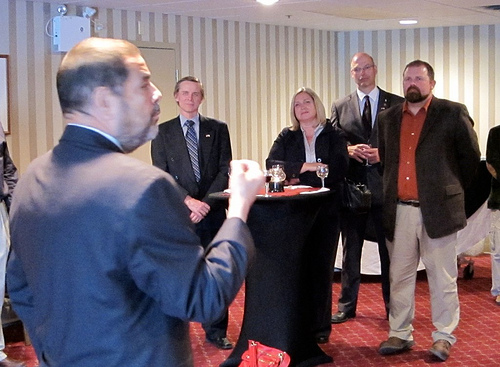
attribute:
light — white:
[399, 17, 419, 29]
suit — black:
[10, 132, 258, 364]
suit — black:
[156, 117, 230, 209]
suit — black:
[330, 92, 392, 317]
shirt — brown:
[335, 119, 493, 219]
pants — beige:
[388, 197, 461, 342]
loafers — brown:
[374, 323, 459, 365]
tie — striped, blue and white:
[179, 117, 203, 178]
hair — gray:
[56, 37, 141, 114]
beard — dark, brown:
[402, 81, 426, 108]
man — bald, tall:
[332, 41, 429, 293]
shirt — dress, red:
[396, 95, 434, 202]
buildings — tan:
[213, 35, 283, 110]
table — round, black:
[211, 182, 343, 365]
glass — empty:
[315, 161, 330, 188]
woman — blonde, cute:
[238, 57, 350, 336]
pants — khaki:
[377, 197, 464, 344]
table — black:
[195, 176, 335, 349]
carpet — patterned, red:
[262, 276, 476, 365]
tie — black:
[363, 92, 374, 129]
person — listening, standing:
[144, 68, 243, 348]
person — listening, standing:
[259, 77, 352, 330]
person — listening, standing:
[312, 43, 412, 323]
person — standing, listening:
[356, 49, 484, 362]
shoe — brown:
[422, 326, 457, 363]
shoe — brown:
[368, 321, 414, 354]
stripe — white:
[175, 14, 212, 82]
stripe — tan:
[196, 18, 236, 92]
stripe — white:
[277, 32, 306, 86]